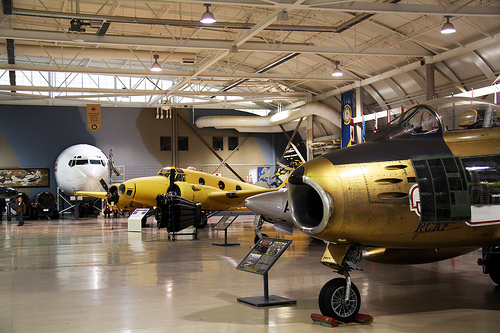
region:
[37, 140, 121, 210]
The white airplane.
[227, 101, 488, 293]
The gold airplane to the right.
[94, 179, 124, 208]
The propeller on the middle plane.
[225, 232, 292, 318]
The sign in front of the gold plane.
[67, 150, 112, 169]
The cockpit on the white plane.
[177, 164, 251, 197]
The windows on the middle plane.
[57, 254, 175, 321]
Shiny floor of an airplane hanger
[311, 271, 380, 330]
Airplane wheel braked on hanger floor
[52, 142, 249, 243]
Two airplanes on display at an aviation museum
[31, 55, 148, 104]
Metal structures at top of aviation housing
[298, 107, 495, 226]
Cockpit of a black and gold plane on display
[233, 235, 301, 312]
Sign detailing airplane at aviation museum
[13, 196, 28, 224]
Man exploring various planes at museum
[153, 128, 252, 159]
Windows on wall at an aviation museum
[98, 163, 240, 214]
Yellow airplane on display at museum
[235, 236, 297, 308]
podium with information on it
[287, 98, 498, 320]
golden plane in a building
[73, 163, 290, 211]
yellow plane with propellers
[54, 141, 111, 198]
white plane in the wall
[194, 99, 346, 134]
white tubes in the ceiling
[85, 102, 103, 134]
yellow banner on the wall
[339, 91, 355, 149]
blue banner hung from rafter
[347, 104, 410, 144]
row of flags hung up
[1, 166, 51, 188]
picture in a frame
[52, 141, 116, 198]
white airplane body without wings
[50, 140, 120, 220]
white airplane body on a stand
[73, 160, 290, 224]
small yellow airplane in a building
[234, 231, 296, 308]
black frame sign on a black base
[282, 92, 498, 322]
gold and black airplane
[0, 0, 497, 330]
four airplanes in a large hangar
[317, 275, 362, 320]
black rubber wheel with chrome rim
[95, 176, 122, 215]
black airplane propellor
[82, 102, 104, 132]
hanging yellow banner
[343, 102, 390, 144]
four hanging flags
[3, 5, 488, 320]
a museum airplane hanger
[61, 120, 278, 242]
a yellow personal plane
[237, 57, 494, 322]
a gold personal plane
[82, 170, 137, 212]
the propeller is black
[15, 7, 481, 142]
white ceiling railing in museum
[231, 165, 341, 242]
silver trim on plane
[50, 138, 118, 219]
the front of a white pilot jet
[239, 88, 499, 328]
an old 20th century plane model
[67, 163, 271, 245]
a large yellow airplane